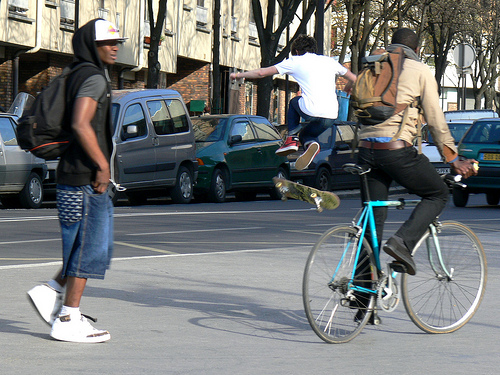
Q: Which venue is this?
A: This is a road.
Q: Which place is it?
A: It is a road.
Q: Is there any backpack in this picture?
A: Yes, there is a backpack.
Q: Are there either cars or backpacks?
A: Yes, there is a backpack.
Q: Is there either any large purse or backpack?
A: Yes, there is a large backpack.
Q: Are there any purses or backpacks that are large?
A: Yes, the backpack is large.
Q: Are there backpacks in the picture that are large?
A: Yes, there is a large backpack.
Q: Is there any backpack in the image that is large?
A: Yes, there is a backpack that is large.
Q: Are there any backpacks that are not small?
A: Yes, there is a large backpack.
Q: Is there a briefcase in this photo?
A: No, there are no briefcases.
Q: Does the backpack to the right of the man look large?
A: Yes, the backpack is large.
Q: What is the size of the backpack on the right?
A: The backpack is large.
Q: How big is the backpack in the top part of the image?
A: The backpack is large.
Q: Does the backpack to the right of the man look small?
A: No, the backpack is large.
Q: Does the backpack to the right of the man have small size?
A: No, the backpack is large.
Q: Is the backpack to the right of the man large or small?
A: The backpack is large.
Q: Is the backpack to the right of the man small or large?
A: The backpack is large.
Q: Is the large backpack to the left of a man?
A: No, the backpack is to the right of a man.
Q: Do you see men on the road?
A: Yes, there is a man on the road.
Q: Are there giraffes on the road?
A: No, there is a man on the road.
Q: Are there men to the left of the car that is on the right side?
A: Yes, there is a man to the left of the car.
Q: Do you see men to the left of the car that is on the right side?
A: Yes, there is a man to the left of the car.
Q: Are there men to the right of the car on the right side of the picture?
A: No, the man is to the left of the car.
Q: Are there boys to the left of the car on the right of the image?
A: No, there is a man to the left of the car.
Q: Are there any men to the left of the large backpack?
A: Yes, there is a man to the left of the backpack.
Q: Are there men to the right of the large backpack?
A: No, the man is to the left of the backpack.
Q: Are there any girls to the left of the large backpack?
A: No, there is a man to the left of the backpack.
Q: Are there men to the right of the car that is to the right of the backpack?
A: Yes, there is a man to the right of the car.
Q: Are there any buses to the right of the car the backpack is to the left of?
A: No, there is a man to the right of the car.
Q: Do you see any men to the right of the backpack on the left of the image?
A: Yes, there is a man to the right of the backpack.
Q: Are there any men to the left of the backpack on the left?
A: No, the man is to the right of the backpack.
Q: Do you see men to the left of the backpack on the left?
A: No, the man is to the right of the backpack.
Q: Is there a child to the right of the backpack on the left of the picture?
A: No, there is a man to the right of the backpack.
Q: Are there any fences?
A: No, there are no fences.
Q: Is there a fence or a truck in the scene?
A: No, there are no fences or trucks.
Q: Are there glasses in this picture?
A: No, there are no glasses.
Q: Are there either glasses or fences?
A: No, there are no glasses or fences.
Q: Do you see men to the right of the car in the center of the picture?
A: Yes, there is a man to the right of the car.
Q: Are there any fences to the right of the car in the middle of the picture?
A: No, there is a man to the right of the car.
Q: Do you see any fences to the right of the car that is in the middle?
A: No, there is a man to the right of the car.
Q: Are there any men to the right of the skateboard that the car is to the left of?
A: Yes, there is a man to the right of the skateboard.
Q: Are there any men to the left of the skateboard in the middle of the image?
A: No, the man is to the right of the skateboard.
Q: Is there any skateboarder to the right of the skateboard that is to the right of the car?
A: No, there is a man to the right of the skateboard.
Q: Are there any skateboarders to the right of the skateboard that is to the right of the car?
A: No, there is a man to the right of the skateboard.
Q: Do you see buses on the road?
A: No, there is a man on the road.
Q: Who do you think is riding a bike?
A: The man is riding a bike.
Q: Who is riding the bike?
A: The man is riding a bike.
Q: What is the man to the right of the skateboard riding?
A: The man is riding a bike.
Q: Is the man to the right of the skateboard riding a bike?
A: Yes, the man is riding a bike.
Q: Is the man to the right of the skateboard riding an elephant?
A: No, the man is riding a bike.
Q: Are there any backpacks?
A: Yes, there is a backpack.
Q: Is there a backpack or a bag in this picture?
A: Yes, there is a backpack.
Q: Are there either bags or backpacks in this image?
A: Yes, there is a backpack.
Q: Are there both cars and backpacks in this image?
A: Yes, there are both a backpack and a car.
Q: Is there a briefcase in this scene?
A: No, there are no briefcases.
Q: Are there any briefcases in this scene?
A: No, there are no briefcases.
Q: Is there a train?
A: No, there are no trains.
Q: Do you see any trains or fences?
A: No, there are no trains or fences.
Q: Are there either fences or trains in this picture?
A: No, there are no trains or fences.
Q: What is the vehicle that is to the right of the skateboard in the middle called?
A: The vehicle is a car.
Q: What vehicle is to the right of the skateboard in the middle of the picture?
A: The vehicle is a car.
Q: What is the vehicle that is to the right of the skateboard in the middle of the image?
A: The vehicle is a car.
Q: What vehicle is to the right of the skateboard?
A: The vehicle is a car.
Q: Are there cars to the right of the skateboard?
A: Yes, there is a car to the right of the skateboard.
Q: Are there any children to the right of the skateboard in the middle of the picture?
A: No, there is a car to the right of the skateboard.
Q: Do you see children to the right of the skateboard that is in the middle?
A: No, there is a car to the right of the skateboard.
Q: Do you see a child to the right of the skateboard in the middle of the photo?
A: No, there is a car to the right of the skateboard.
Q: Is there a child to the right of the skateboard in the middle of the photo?
A: No, there is a car to the right of the skateboard.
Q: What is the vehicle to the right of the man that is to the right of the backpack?
A: The vehicle is a car.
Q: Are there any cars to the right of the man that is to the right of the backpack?
A: Yes, there is a car to the right of the man.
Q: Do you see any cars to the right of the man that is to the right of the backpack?
A: Yes, there is a car to the right of the man.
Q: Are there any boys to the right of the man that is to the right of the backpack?
A: No, there is a car to the right of the man.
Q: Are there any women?
A: No, there are no women.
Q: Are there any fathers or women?
A: No, there are no women or fathers.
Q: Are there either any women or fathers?
A: No, there are no women or fathers.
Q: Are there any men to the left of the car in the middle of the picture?
A: Yes, there is a man to the left of the car.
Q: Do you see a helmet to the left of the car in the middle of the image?
A: No, there is a man to the left of the car.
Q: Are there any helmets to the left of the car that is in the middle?
A: No, there is a man to the left of the car.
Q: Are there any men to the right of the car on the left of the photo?
A: Yes, there is a man to the right of the car.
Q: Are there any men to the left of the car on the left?
A: No, the man is to the right of the car.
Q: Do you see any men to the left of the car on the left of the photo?
A: No, the man is to the right of the car.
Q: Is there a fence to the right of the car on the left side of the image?
A: No, there is a man to the right of the car.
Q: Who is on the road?
A: The man is on the road.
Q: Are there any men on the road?
A: Yes, there is a man on the road.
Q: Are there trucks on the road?
A: No, there is a man on the road.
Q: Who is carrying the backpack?
A: The man is carrying the backpack.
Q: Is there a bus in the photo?
A: No, there are no buses.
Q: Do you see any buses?
A: No, there are no buses.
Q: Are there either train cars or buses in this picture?
A: No, there are no buses or train cars.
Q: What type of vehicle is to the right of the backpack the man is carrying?
A: The vehicle is a car.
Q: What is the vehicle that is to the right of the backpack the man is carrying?
A: The vehicle is a car.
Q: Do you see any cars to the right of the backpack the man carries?
A: Yes, there is a car to the right of the backpack.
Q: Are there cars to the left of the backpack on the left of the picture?
A: No, the car is to the right of the backpack.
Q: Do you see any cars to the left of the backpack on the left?
A: No, the car is to the right of the backpack.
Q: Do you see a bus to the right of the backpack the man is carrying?
A: No, there is a car to the right of the backpack.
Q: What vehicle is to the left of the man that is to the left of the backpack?
A: The vehicle is a car.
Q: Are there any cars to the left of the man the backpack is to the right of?
A: Yes, there is a car to the left of the man.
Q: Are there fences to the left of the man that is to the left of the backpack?
A: No, there is a car to the left of the man.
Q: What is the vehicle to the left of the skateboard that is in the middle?
A: The vehicle is a car.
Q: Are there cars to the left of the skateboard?
A: Yes, there is a car to the left of the skateboard.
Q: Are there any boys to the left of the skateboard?
A: No, there is a car to the left of the skateboard.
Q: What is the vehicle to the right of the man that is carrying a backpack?
A: The vehicle is a car.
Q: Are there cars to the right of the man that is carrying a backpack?
A: Yes, there is a car to the right of the man.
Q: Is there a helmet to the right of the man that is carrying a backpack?
A: No, there is a car to the right of the man.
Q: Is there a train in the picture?
A: No, there are no trains.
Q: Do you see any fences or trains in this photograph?
A: No, there are no trains or fences.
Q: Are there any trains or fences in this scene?
A: No, there are no trains or fences.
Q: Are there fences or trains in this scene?
A: No, there are no trains or fences.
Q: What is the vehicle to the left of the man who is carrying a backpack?
A: The vehicle is a car.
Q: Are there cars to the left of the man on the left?
A: Yes, there is a car to the left of the man.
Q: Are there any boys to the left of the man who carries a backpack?
A: No, there is a car to the left of the man.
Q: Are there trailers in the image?
A: No, there are no trailers.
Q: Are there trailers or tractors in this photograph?
A: No, there are no trailers or tractors.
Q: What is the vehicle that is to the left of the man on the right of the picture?
A: The vehicle is a car.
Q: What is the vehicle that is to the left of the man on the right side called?
A: The vehicle is a car.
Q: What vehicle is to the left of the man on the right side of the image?
A: The vehicle is a car.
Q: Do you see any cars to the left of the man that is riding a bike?
A: Yes, there is a car to the left of the man.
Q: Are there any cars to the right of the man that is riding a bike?
A: No, the car is to the left of the man.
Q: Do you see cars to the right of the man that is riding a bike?
A: No, the car is to the left of the man.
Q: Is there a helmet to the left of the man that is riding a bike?
A: No, there is a car to the left of the man.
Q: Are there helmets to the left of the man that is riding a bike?
A: No, there is a car to the left of the man.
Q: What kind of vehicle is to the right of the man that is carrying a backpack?
A: The vehicle is a car.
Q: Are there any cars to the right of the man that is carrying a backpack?
A: Yes, there is a car to the right of the man.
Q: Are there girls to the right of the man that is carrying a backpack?
A: No, there is a car to the right of the man.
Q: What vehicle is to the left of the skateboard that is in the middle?
A: The vehicle is a car.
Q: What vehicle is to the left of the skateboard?
A: The vehicle is a car.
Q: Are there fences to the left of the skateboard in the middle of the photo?
A: No, there is a car to the left of the skateboard.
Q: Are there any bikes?
A: Yes, there is a bike.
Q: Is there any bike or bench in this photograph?
A: Yes, there is a bike.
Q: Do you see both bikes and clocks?
A: No, there is a bike but no clocks.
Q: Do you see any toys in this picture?
A: No, there are no toys.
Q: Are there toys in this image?
A: No, there are no toys.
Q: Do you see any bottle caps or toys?
A: No, there are no toys or bottle caps.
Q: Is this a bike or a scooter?
A: This is a bike.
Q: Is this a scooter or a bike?
A: This is a bike.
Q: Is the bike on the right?
A: Yes, the bike is on the right of the image.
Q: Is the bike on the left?
A: No, the bike is on the right of the image.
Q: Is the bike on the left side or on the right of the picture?
A: The bike is on the right of the image.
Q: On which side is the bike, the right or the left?
A: The bike is on the right of the image.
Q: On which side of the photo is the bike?
A: The bike is on the right of the image.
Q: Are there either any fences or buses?
A: No, there are no buses or fences.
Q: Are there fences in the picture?
A: No, there are no fences.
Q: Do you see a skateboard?
A: Yes, there is a skateboard.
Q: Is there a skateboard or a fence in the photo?
A: Yes, there is a skateboard.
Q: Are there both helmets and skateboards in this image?
A: No, there is a skateboard but no helmets.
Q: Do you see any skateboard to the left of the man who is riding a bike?
A: Yes, there is a skateboard to the left of the man.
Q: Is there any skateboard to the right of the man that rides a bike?
A: No, the skateboard is to the left of the man.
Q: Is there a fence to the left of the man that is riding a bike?
A: No, there is a skateboard to the left of the man.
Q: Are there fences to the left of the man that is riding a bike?
A: No, there is a skateboard to the left of the man.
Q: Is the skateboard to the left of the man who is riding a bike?
A: Yes, the skateboard is to the left of the man.